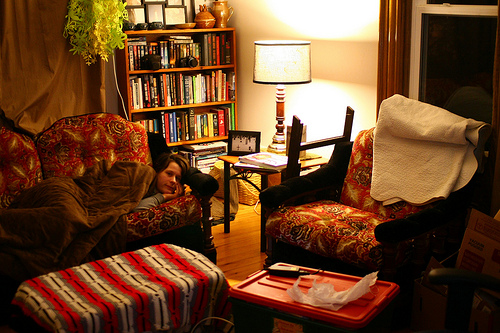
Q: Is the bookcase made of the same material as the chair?
A: Yes, both the bookcase and the chair are made of wood.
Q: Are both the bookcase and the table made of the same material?
A: Yes, both the bookcase and the table are made of wood.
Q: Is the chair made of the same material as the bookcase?
A: Yes, both the chair and the bookcase are made of wood.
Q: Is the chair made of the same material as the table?
A: Yes, both the chair and the table are made of wood.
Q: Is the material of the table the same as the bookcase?
A: Yes, both the table and the bookcase are made of wood.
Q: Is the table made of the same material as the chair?
A: Yes, both the table and the chair are made of wood.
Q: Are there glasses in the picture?
A: No, there are no glasses.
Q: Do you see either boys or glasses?
A: No, there are no glasses or boys.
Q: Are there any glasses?
A: No, there are no glasses.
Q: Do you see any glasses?
A: No, there are no glasses.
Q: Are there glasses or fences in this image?
A: No, there are no glasses or fences.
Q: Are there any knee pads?
A: No, there are no knee pads.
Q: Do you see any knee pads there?
A: No, there are no knee pads.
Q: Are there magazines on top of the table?
A: Yes, there is a magazine on top of the table.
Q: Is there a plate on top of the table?
A: No, there is a magazine on top of the table.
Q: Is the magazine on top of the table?
A: Yes, the magazine is on top of the table.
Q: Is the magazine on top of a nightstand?
A: No, the magazine is on top of the table.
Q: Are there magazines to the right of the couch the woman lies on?
A: Yes, there is a magazine to the right of the couch.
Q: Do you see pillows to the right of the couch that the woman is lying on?
A: No, there is a magazine to the right of the couch.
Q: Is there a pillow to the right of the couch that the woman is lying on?
A: No, there is a magazine to the right of the couch.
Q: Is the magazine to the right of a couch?
A: Yes, the magazine is to the right of a couch.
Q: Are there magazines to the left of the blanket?
A: Yes, there is a magazine to the left of the blanket.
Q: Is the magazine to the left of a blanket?
A: Yes, the magazine is to the left of a blanket.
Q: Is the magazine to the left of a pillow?
A: No, the magazine is to the left of a blanket.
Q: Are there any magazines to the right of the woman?
A: Yes, there is a magazine to the right of the woman.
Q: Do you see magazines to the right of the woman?
A: Yes, there is a magazine to the right of the woman.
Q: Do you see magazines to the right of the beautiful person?
A: Yes, there is a magazine to the right of the woman.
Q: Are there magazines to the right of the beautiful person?
A: Yes, there is a magazine to the right of the woman.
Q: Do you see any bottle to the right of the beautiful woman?
A: No, there is a magazine to the right of the woman.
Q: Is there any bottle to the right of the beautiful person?
A: No, there is a magazine to the right of the woman.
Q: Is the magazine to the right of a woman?
A: Yes, the magazine is to the right of a woman.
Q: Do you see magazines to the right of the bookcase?
A: Yes, there is a magazine to the right of the bookcase.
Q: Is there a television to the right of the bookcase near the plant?
A: No, there is a magazine to the right of the bookcase.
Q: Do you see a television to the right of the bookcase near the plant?
A: No, there is a magazine to the right of the bookcase.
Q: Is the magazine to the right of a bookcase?
A: Yes, the magazine is to the right of a bookcase.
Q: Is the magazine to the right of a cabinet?
A: No, the magazine is to the right of a bookcase.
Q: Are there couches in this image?
A: Yes, there is a couch.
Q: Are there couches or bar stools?
A: Yes, there is a couch.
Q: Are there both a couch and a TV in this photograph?
A: No, there is a couch but no televisions.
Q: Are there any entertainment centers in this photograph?
A: No, there are no entertainment centers.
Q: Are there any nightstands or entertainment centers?
A: No, there are no entertainment centers or nightstands.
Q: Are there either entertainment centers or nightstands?
A: No, there are no entertainment centers or nightstands.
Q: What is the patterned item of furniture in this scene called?
A: The piece of furniture is a couch.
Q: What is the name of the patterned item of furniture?
A: The piece of furniture is a couch.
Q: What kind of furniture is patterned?
A: The furniture is a couch.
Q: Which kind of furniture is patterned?
A: The furniture is a couch.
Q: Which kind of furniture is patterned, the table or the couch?
A: The couch is patterned.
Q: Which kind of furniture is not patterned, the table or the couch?
A: The table is not patterned.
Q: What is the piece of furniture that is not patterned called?
A: The piece of furniture is a table.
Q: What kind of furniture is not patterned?
A: The furniture is a table.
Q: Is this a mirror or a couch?
A: This is a couch.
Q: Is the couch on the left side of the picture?
A: Yes, the couch is on the left of the image.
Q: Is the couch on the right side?
A: No, the couch is on the left of the image.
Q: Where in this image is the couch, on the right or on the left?
A: The couch is on the left of the image.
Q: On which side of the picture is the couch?
A: The couch is on the left of the image.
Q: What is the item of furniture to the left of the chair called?
A: The piece of furniture is a couch.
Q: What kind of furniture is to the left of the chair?
A: The piece of furniture is a couch.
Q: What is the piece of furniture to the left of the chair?
A: The piece of furniture is a couch.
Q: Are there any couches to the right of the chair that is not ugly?
A: No, the couch is to the left of the chair.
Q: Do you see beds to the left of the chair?
A: No, there is a couch to the left of the chair.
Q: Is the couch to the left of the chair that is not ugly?
A: Yes, the couch is to the left of the chair.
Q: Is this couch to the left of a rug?
A: No, the couch is to the left of the chair.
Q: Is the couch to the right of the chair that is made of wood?
A: No, the couch is to the left of the chair.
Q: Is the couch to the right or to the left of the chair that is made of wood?
A: The couch is to the left of the chair.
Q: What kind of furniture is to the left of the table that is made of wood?
A: The piece of furniture is a couch.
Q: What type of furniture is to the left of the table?
A: The piece of furniture is a couch.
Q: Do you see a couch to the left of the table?
A: Yes, there is a couch to the left of the table.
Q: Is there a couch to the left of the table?
A: Yes, there is a couch to the left of the table.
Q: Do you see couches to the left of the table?
A: Yes, there is a couch to the left of the table.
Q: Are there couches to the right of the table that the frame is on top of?
A: No, the couch is to the left of the table.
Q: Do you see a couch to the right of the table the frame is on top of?
A: No, the couch is to the left of the table.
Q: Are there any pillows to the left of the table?
A: No, there is a couch to the left of the table.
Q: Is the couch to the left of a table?
A: Yes, the couch is to the left of a table.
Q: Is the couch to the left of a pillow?
A: No, the couch is to the left of a table.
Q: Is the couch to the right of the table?
A: No, the couch is to the left of the table.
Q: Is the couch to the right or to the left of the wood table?
A: The couch is to the left of the table.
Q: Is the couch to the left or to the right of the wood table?
A: The couch is to the left of the table.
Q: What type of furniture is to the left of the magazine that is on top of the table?
A: The piece of furniture is a couch.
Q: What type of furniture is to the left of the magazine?
A: The piece of furniture is a couch.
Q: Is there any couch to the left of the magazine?
A: Yes, there is a couch to the left of the magazine.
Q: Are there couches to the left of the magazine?
A: Yes, there is a couch to the left of the magazine.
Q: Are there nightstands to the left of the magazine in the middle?
A: No, there is a couch to the left of the magazine.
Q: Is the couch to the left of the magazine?
A: Yes, the couch is to the left of the magazine.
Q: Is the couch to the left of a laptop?
A: No, the couch is to the left of the magazine.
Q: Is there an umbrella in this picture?
A: No, there are no umbrellas.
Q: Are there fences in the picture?
A: No, there are no fences.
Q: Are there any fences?
A: No, there are no fences.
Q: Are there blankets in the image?
A: Yes, there is a blanket.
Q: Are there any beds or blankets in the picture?
A: Yes, there is a blanket.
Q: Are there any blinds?
A: No, there are no blinds.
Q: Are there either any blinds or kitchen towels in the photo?
A: No, there are no blinds or kitchen towels.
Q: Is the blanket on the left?
A: No, the blanket is on the right of the image.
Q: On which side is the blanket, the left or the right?
A: The blanket is on the right of the image.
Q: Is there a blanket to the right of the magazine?
A: Yes, there is a blanket to the right of the magazine.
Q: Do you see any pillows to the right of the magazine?
A: No, there is a blanket to the right of the magazine.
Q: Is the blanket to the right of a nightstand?
A: No, the blanket is to the right of a magazine.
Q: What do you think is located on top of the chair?
A: The blanket is on top of the chair.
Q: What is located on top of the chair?
A: The blanket is on top of the chair.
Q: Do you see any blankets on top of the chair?
A: Yes, there is a blanket on top of the chair.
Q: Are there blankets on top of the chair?
A: Yes, there is a blanket on top of the chair.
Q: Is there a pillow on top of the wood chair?
A: No, there is a blanket on top of the chair.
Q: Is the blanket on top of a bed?
A: No, the blanket is on top of the chair.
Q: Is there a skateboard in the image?
A: No, there are no skateboards.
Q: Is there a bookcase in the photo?
A: Yes, there is a bookcase.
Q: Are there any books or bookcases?
A: Yes, there is a bookcase.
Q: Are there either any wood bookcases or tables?
A: Yes, there is a wood bookcase.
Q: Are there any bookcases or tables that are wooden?
A: Yes, the bookcase is wooden.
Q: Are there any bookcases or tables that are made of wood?
A: Yes, the bookcase is made of wood.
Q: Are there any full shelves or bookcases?
A: Yes, there is a full bookcase.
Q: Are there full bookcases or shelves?
A: Yes, there is a full bookcase.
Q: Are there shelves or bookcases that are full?
A: Yes, the bookcase is full.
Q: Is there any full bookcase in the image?
A: Yes, there is a full bookcase.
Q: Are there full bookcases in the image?
A: Yes, there is a full bookcase.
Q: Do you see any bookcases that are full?
A: Yes, there is a bookcase that is full.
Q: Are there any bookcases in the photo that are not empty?
A: Yes, there is an full bookcase.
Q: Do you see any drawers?
A: No, there are no drawers.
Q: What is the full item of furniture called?
A: The piece of furniture is a bookcase.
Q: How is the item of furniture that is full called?
A: The piece of furniture is a bookcase.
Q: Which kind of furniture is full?
A: The furniture is a bookcase.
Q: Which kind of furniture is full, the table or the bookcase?
A: The bookcase is full.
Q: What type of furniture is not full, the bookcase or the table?
A: The table is not full.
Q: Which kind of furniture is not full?
A: The furniture is a table.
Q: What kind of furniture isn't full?
A: The furniture is a table.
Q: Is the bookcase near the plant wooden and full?
A: Yes, the bookcase is wooden and full.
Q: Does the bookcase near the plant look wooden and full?
A: Yes, the bookcase is wooden and full.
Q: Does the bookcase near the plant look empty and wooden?
A: No, the bookcase is wooden but full.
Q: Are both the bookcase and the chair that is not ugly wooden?
A: Yes, both the bookcase and the chair are wooden.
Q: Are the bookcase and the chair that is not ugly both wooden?
A: Yes, both the bookcase and the chair are wooden.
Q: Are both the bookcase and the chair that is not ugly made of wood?
A: Yes, both the bookcase and the chair are made of wood.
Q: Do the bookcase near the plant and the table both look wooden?
A: Yes, both the bookcase and the table are wooden.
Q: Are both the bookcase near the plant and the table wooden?
A: Yes, both the bookcase and the table are wooden.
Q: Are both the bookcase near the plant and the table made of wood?
A: Yes, both the bookcase and the table are made of wood.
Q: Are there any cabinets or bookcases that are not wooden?
A: No, there is a bookcase but it is wooden.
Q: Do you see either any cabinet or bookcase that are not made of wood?
A: No, there is a bookcase but it is made of wood.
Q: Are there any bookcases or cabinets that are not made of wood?
A: No, there is a bookcase but it is made of wood.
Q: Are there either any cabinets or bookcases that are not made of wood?
A: No, there is a bookcase but it is made of wood.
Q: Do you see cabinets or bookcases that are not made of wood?
A: No, there is a bookcase but it is made of wood.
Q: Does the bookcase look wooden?
A: Yes, the bookcase is wooden.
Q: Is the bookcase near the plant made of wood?
A: Yes, the bookcase is made of wood.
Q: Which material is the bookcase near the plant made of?
A: The bookcase is made of wood.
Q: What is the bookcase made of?
A: The bookcase is made of wood.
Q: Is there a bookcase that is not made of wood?
A: No, there is a bookcase but it is made of wood.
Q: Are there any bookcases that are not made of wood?
A: No, there is a bookcase but it is made of wood.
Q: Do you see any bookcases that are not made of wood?
A: No, there is a bookcase but it is made of wood.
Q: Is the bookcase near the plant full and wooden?
A: Yes, the bookcase is full and wooden.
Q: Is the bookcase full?
A: Yes, the bookcase is full.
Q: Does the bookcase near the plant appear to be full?
A: Yes, the bookcase is full.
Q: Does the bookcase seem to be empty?
A: No, the bookcase is full.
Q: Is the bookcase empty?
A: No, the bookcase is full.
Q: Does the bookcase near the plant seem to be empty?
A: No, the bookcase is full.